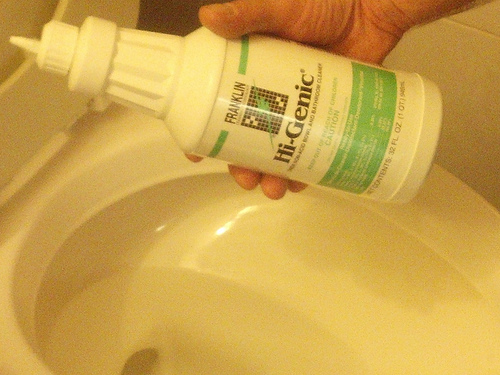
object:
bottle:
[7, 15, 444, 204]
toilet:
[1, 1, 497, 374]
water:
[45, 264, 363, 374]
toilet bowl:
[1, 96, 498, 374]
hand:
[185, 1, 488, 199]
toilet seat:
[1, 1, 145, 187]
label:
[198, 29, 409, 201]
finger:
[229, 164, 261, 191]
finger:
[263, 174, 290, 201]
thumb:
[198, 0, 342, 40]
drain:
[121, 347, 173, 374]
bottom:
[386, 69, 444, 205]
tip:
[9, 31, 44, 59]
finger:
[185, 153, 205, 163]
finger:
[289, 175, 307, 193]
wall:
[380, 1, 499, 216]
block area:
[315, 62, 397, 197]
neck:
[85, 21, 186, 119]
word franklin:
[220, 79, 249, 129]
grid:
[239, 85, 288, 134]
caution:
[323, 107, 343, 150]